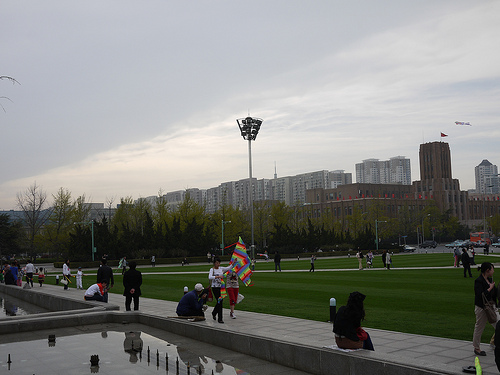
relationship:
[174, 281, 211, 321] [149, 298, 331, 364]
man sitting on cement ledge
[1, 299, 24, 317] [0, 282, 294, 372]
water in pond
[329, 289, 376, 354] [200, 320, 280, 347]
woman sitting on ledge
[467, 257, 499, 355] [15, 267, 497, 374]
woman walking on sidewalk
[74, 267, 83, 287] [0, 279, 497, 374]
child on sidewalk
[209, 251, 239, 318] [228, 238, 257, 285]
woman holding kite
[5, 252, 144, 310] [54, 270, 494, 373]
people on a sidewalk